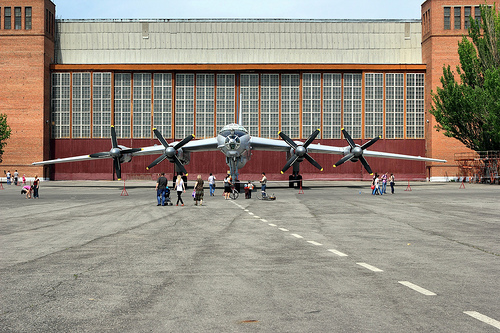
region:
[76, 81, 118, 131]
large group of clear windows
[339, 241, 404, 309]
white painted lines on ground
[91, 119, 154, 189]
large silver propeller on left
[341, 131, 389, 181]
large dark propeller on the right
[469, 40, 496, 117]
tall green leafy tree on right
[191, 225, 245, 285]
dark lines on asphalt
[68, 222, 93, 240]
grey area of asphalt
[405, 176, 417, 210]
orange safety triangle on ground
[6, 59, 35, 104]
red brick column on left side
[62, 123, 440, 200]
silver plane in middle of photo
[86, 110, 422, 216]
the propellers are black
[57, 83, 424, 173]
the propellers are black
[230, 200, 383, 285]
the white lines on the ground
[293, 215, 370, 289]
the white lines on the ground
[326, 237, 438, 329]
the white lines on the ground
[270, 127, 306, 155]
the propeller is black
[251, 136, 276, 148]
the plane is silver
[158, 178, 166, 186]
the shirt is black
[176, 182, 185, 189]
the shirt is white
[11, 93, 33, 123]
the building is brown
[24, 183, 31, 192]
the shirt is pink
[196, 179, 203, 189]
the shirt is brown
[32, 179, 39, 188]
the shirt is red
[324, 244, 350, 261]
the line is white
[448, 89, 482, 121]
the leaves are green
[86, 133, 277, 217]
several people viewing a plane on exhibit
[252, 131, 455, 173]
the wing of a plane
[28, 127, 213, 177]
the wing of a plane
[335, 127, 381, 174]
the prop of a plane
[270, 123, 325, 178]
the prop of a plane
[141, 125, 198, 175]
the prop of a plane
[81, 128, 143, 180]
the prop of a plane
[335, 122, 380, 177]
the propeller of a plane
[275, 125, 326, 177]
the propeller of a plane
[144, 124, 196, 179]
the propeller of a plane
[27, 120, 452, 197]
jet on a display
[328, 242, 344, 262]
white dash on road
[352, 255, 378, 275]
white dash on road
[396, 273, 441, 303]
white dash on road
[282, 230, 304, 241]
white dash on road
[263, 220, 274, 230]
white dash on road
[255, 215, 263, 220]
white dash on road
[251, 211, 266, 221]
white dash on road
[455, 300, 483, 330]
white dash on road